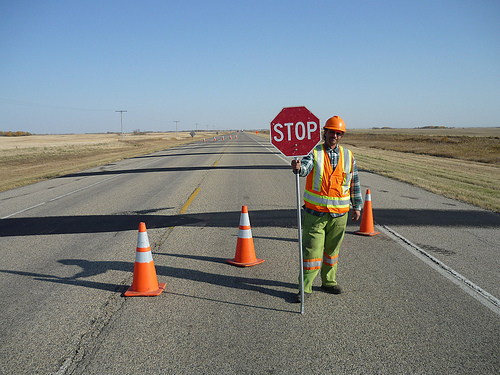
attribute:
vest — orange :
[307, 143, 355, 213]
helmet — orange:
[319, 112, 349, 136]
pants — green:
[295, 194, 346, 292]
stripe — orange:
[303, 253, 329, 263]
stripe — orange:
[301, 262, 325, 270]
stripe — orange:
[324, 253, 343, 259]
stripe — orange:
[317, 261, 337, 269]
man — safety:
[292, 111, 366, 305]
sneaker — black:
[292, 289, 314, 303]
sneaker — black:
[317, 281, 341, 294]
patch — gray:
[311, 147, 325, 191]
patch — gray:
[341, 148, 351, 201]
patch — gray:
[303, 190, 354, 206]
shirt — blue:
[298, 142, 363, 212]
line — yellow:
[173, 141, 228, 220]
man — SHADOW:
[284, 93, 374, 273]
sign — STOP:
[244, 102, 334, 162]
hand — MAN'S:
[292, 152, 302, 171]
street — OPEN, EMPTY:
[204, 128, 252, 196]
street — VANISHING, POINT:
[185, 137, 259, 335]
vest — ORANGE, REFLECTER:
[313, 160, 350, 207]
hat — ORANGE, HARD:
[309, 122, 354, 140]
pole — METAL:
[299, 192, 303, 306]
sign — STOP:
[272, 107, 329, 302]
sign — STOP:
[259, 99, 327, 310]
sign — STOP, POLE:
[265, 109, 321, 305]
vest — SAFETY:
[312, 151, 352, 217]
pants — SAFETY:
[300, 206, 343, 285]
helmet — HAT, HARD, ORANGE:
[328, 116, 342, 134]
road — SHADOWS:
[190, 268, 248, 345]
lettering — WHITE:
[278, 118, 318, 136]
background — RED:
[286, 105, 295, 110]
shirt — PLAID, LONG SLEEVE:
[356, 176, 366, 197]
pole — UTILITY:
[116, 120, 131, 141]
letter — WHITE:
[276, 126, 316, 139]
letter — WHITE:
[272, 119, 316, 138]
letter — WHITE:
[276, 130, 311, 150]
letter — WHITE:
[273, 118, 316, 134]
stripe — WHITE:
[137, 231, 154, 246]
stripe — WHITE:
[135, 230, 148, 243]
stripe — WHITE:
[141, 233, 149, 241]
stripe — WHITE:
[133, 228, 149, 251]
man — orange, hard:
[291, 114, 361, 300]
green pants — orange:
[297, 205, 348, 291]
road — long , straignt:
[1, 130, 498, 372]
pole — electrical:
[112, 106, 129, 130]